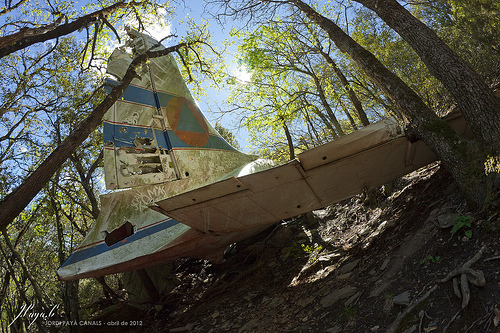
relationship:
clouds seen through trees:
[94, 8, 258, 102] [194, 26, 468, 203]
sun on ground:
[273, 194, 391, 286] [149, 165, 498, 331]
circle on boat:
[164, 95, 212, 147] [48, 27, 478, 278]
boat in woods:
[67, 37, 452, 247] [1, 1, 498, 327]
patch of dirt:
[340, 202, 405, 259] [281, 253, 386, 293]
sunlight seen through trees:
[100, 7, 219, 73] [71, 5, 374, 205]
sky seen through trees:
[0, 0, 370, 80] [212, 18, 387, 171]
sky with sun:
[24, 50, 70, 79] [187, 26, 231, 88]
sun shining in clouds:
[187, 26, 231, 88] [220, 53, 252, 80]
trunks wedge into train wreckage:
[296, 5, 498, 216] [49, 24, 495, 286]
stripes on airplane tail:
[90, 69, 237, 169] [26, 26, 496, 292]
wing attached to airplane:
[153, 116, 466, 243] [54, 27, 495, 286]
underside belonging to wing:
[146, 114, 466, 243] [153, 116, 466, 243]